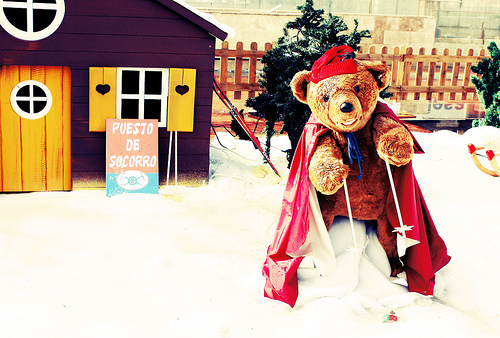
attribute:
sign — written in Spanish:
[101, 116, 162, 198]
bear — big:
[255, 29, 452, 336]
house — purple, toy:
[0, 2, 231, 188]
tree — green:
[247, 1, 396, 168]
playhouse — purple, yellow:
[1, 0, 218, 201]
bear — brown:
[260, 39, 447, 289]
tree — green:
[458, 38, 498, 139]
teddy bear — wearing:
[281, 36, 419, 281]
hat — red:
[307, 39, 368, 84]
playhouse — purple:
[10, 6, 223, 212]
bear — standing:
[287, 43, 417, 288]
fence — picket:
[398, 44, 486, 106]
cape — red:
[278, 119, 446, 320]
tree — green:
[252, 0, 382, 177]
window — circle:
[12, 77, 55, 118]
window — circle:
[7, 72, 53, 124]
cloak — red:
[269, 115, 439, 300]